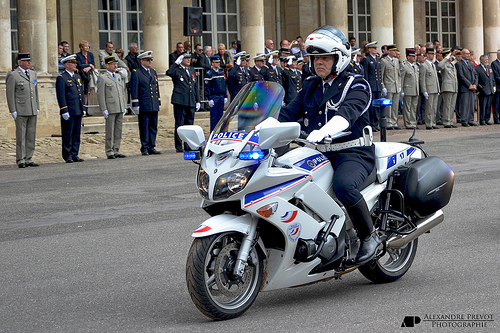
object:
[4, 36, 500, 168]
crowd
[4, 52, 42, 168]
men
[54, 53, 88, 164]
men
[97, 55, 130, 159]
men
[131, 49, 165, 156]
men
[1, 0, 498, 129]
building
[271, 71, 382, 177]
dress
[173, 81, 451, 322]
motorcycle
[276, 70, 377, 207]
uniform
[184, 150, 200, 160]
light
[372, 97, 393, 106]
light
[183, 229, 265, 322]
tire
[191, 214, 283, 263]
cover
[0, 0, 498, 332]
photo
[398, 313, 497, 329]
watermark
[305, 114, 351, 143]
glove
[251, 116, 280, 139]
glove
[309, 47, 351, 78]
head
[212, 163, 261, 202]
headlight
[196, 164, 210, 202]
headlight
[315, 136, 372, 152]
belt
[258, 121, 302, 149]
mirror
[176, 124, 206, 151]
mirror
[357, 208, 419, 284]
tire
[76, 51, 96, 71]
jacket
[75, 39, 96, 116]
woman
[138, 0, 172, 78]
column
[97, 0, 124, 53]
window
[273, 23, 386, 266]
policeman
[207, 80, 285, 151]
shield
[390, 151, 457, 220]
box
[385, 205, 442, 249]
pipe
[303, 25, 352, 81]
helmet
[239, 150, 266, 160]
light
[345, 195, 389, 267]
boot